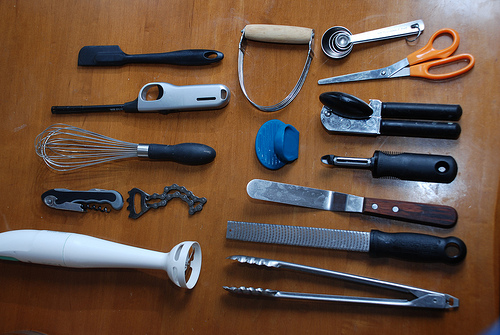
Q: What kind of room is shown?
A: It is a kitchen.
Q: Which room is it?
A: It is a kitchen.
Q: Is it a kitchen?
A: Yes, it is a kitchen.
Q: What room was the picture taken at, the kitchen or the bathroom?
A: It was taken at the kitchen.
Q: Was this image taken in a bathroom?
A: No, the picture was taken in a kitchen.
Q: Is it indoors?
A: Yes, it is indoors.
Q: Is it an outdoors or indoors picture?
A: It is indoors.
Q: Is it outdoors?
A: No, it is indoors.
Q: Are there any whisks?
A: Yes, there is a whisk.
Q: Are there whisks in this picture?
A: Yes, there is a whisk.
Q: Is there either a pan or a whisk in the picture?
A: Yes, there is a whisk.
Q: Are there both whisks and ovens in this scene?
A: No, there is a whisk but no ovens.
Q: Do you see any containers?
A: No, there are no containers.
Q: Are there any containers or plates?
A: No, there are no containers or plates.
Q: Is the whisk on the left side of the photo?
A: Yes, the whisk is on the left of the image.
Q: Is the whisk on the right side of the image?
A: No, the whisk is on the left of the image.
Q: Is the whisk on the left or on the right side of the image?
A: The whisk is on the left of the image.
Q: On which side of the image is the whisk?
A: The whisk is on the left of the image.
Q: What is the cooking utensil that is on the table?
A: The cooking utensil is a whisk.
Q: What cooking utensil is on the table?
A: The cooking utensil is a whisk.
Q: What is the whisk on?
A: The whisk is on the table.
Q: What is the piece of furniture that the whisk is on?
A: The piece of furniture is a table.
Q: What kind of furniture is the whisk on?
A: The whisk is on the table.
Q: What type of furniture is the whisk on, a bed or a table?
A: The whisk is on a table.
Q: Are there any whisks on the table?
A: Yes, there is a whisk on the table.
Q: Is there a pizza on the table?
A: No, there is a whisk on the table.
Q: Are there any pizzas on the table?
A: No, there is a whisk on the table.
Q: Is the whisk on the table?
A: Yes, the whisk is on the table.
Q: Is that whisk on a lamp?
A: No, the whisk is on the table.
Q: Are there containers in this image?
A: No, there are no containers.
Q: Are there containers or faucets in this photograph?
A: No, there are no containers or faucets.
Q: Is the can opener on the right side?
A: Yes, the can opener is on the right of the image.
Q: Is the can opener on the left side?
A: No, the can opener is on the right of the image.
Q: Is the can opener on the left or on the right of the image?
A: The can opener is on the right of the image.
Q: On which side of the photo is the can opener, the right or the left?
A: The can opener is on the right of the image.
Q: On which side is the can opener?
A: The can opener is on the right of the image.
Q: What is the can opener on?
A: The can opener is on the table.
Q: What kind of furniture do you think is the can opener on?
A: The can opener is on the table.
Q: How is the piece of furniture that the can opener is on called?
A: The piece of furniture is a table.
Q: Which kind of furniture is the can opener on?
A: The can opener is on the table.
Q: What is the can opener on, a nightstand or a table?
A: The can opener is on a table.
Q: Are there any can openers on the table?
A: Yes, there is a can opener on the table.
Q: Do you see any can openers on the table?
A: Yes, there is a can opener on the table.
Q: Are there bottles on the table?
A: No, there is a can opener on the table.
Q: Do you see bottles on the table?
A: No, there is a can opener on the table.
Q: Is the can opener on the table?
A: Yes, the can opener is on the table.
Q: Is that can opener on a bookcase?
A: No, the can opener is on the table.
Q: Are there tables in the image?
A: Yes, there is a table.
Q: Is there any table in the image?
A: Yes, there is a table.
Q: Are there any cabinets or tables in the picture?
A: Yes, there is a table.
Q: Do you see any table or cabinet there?
A: Yes, there is a table.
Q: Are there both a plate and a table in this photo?
A: No, there is a table but no plates.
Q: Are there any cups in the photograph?
A: No, there are no cups.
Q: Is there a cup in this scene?
A: No, there are no cups.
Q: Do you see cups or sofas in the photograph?
A: No, there are no cups or sofas.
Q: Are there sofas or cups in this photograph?
A: No, there are no cups or sofas.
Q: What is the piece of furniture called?
A: The piece of furniture is a table.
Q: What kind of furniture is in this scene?
A: The furniture is a table.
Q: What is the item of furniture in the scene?
A: The piece of furniture is a table.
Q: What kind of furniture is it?
A: The piece of furniture is a table.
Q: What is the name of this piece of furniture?
A: This is a table.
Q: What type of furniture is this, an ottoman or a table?
A: This is a table.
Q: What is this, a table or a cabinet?
A: This is a table.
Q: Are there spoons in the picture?
A: Yes, there is a spoon.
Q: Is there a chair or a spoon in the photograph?
A: Yes, there is a spoon.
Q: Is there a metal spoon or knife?
A: Yes, there is a metal spoon.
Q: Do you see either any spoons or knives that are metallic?
A: Yes, the spoon is metallic.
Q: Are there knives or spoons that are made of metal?
A: Yes, the spoon is made of metal.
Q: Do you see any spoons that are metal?
A: Yes, there is a metal spoon.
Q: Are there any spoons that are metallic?
A: Yes, there is a spoon that is metallic.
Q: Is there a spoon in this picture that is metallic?
A: Yes, there is a spoon that is metallic.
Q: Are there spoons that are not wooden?
A: Yes, there is a metallic spoon.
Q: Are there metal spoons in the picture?
A: Yes, there is a spoon that is made of metal.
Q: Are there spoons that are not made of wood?
A: Yes, there is a spoon that is made of metal.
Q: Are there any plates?
A: No, there are no plates.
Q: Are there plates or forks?
A: No, there are no plates or forks.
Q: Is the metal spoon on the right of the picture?
A: Yes, the spoon is on the right of the image.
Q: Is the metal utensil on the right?
A: Yes, the spoon is on the right of the image.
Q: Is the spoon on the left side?
A: No, the spoon is on the right of the image.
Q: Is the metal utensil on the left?
A: No, the spoon is on the right of the image.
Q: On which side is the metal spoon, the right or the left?
A: The spoon is on the right of the image.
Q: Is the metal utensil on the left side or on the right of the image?
A: The spoon is on the right of the image.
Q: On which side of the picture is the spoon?
A: The spoon is on the right of the image.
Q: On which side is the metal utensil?
A: The spoon is on the right of the image.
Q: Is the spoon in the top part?
A: Yes, the spoon is in the top of the image.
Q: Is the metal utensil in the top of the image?
A: Yes, the spoon is in the top of the image.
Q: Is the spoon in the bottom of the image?
A: No, the spoon is in the top of the image.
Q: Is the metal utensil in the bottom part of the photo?
A: No, the spoon is in the top of the image.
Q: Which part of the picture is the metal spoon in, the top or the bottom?
A: The spoon is in the top of the image.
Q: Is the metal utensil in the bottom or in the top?
A: The spoon is in the top of the image.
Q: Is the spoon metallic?
A: Yes, the spoon is metallic.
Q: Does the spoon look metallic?
A: Yes, the spoon is metallic.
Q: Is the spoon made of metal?
A: Yes, the spoon is made of metal.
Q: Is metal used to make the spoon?
A: Yes, the spoon is made of metal.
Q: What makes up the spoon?
A: The spoon is made of metal.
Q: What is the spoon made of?
A: The spoon is made of metal.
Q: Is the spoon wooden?
A: No, the spoon is metallic.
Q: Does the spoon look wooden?
A: No, the spoon is metallic.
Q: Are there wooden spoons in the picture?
A: No, there is a spoon but it is metallic.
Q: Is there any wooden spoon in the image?
A: No, there is a spoon but it is metallic.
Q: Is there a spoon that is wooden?
A: No, there is a spoon but it is metallic.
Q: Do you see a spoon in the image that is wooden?
A: No, there is a spoon but it is metallic.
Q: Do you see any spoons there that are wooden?
A: No, there is a spoon but it is metallic.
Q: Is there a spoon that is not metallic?
A: No, there is a spoon but it is metallic.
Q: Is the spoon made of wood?
A: No, the spoon is made of metal.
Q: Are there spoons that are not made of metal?
A: No, there is a spoon but it is made of metal.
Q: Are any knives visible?
A: Yes, there is a knife.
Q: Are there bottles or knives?
A: Yes, there is a knife.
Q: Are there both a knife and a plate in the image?
A: No, there is a knife but no plates.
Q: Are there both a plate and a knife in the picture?
A: No, there is a knife but no plates.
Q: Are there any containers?
A: No, there are no containers.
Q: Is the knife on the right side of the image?
A: Yes, the knife is on the right of the image.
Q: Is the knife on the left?
A: No, the knife is on the right of the image.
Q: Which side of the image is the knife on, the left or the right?
A: The knife is on the right of the image.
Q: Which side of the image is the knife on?
A: The knife is on the right of the image.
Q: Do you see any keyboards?
A: No, there are no keyboards.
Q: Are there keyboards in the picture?
A: No, there are no keyboards.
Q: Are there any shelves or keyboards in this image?
A: No, there are no keyboards or shelves.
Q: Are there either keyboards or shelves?
A: No, there are no keyboards or shelves.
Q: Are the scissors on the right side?
A: Yes, the scissors are on the right of the image.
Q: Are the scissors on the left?
A: No, the scissors are on the right of the image.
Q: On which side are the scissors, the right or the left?
A: The scissors are on the right of the image.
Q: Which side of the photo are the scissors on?
A: The scissors are on the right of the image.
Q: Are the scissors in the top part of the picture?
A: Yes, the scissors are in the top of the image.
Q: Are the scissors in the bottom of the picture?
A: No, the scissors are in the top of the image.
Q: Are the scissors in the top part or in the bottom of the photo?
A: The scissors are in the top of the image.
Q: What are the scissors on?
A: The scissors are on the table.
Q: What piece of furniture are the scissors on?
A: The scissors are on the table.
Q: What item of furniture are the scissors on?
A: The scissors are on the table.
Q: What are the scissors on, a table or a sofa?
A: The scissors are on a table.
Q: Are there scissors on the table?
A: Yes, there are scissors on the table.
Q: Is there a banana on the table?
A: No, there are scissors on the table.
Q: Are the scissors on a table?
A: Yes, the scissors are on a table.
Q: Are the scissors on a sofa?
A: No, the scissors are on a table.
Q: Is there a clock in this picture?
A: No, there are no clocks.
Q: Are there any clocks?
A: No, there are no clocks.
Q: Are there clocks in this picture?
A: No, there are no clocks.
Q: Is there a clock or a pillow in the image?
A: No, there are no clocks or pillows.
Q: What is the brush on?
A: The brush is on the table.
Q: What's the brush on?
A: The brush is on the table.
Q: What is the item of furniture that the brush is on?
A: The piece of furniture is a table.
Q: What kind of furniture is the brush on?
A: The brush is on the table.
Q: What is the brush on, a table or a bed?
A: The brush is on a table.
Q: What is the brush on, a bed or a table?
A: The brush is on a table.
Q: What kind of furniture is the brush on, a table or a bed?
A: The brush is on a table.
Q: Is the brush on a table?
A: Yes, the brush is on a table.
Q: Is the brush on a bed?
A: No, the brush is on a table.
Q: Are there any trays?
A: No, there are no trays.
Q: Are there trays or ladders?
A: No, there are no trays or ladders.